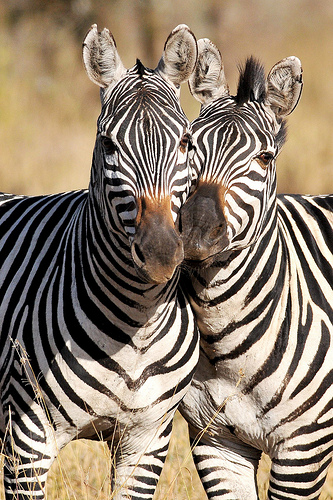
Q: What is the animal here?
A: Zebra.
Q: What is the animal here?
A: Zebras.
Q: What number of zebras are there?
A: 2.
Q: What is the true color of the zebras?
A: Black and white.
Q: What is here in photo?
A: Zebras.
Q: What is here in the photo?
A: Zebras.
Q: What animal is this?
A: Zebra.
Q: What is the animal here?
A: Zebras.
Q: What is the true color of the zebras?
A: Black and white.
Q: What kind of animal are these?
A: Zebra.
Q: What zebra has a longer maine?
A: The one on the right.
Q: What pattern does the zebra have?
A: Striped.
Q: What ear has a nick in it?
A: Far left.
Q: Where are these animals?
A: Wilderness.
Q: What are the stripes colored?
A: Black and white.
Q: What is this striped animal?
A: Zebra.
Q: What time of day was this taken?
A: Afternoon.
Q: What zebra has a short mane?
A: Left one.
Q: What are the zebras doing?
A: Nuzzling.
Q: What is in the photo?
A: Zebras.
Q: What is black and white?
A: The zebras.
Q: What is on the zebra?
A: Stripes.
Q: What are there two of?
A: Zebras.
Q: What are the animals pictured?
A: Zebra.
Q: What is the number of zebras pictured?
A: 2.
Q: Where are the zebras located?
A: Field.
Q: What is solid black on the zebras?
A: Nose.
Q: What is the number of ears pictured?
A: 4.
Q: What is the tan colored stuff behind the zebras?
A: Grass.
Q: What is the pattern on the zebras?
A: Stripe.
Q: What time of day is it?
A: Daytime.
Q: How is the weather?
A: Sunny.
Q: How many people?
A: None.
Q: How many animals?
A: Two.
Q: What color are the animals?
A: Black and white.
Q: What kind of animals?
A: Zebras.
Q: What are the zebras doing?
A: Nuzzling.